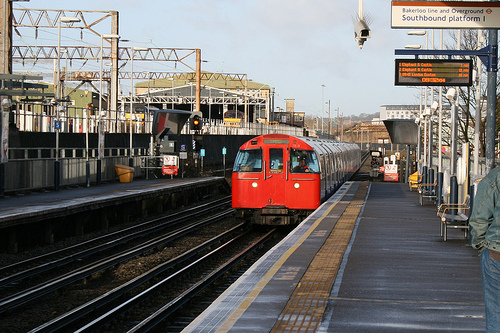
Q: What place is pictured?
A: It is a station.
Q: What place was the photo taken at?
A: It was taken at the station.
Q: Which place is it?
A: It is a station.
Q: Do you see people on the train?
A: Yes, there is a person on the train.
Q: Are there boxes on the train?
A: No, there is a person on the train.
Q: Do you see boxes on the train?
A: No, there is a person on the train.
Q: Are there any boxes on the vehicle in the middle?
A: No, there is a person on the train.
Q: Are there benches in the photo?
A: Yes, there is a bench.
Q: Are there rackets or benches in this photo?
A: Yes, there is a bench.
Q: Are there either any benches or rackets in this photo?
A: Yes, there is a bench.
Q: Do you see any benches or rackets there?
A: Yes, there is a bench.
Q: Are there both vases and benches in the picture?
A: No, there is a bench but no vases.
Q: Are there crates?
A: No, there are no crates.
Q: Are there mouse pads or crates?
A: No, there are no crates or mouse pads.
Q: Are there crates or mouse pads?
A: No, there are no crates or mouse pads.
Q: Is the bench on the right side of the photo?
A: Yes, the bench is on the right of the image.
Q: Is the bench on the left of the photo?
A: No, the bench is on the right of the image.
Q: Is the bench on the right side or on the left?
A: The bench is on the right of the image.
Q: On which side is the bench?
A: The bench is on the right of the image.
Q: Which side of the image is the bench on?
A: The bench is on the right of the image.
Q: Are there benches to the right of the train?
A: Yes, there is a bench to the right of the train.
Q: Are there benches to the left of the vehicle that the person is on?
A: No, the bench is to the right of the train.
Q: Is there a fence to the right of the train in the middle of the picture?
A: No, there is a bench to the right of the train.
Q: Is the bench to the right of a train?
A: Yes, the bench is to the right of a train.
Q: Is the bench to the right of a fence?
A: No, the bench is to the right of a train.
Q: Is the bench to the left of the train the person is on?
A: No, the bench is to the right of the train.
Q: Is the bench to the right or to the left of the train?
A: The bench is to the right of the train.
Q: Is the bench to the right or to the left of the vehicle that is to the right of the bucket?
A: The bench is to the right of the train.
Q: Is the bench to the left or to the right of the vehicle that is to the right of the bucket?
A: The bench is to the right of the train.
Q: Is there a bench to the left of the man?
A: Yes, there is a bench to the left of the man.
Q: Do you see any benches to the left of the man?
A: Yes, there is a bench to the left of the man.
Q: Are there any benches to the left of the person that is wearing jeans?
A: Yes, there is a bench to the left of the man.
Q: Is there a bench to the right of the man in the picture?
A: No, the bench is to the left of the man.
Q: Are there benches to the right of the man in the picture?
A: No, the bench is to the left of the man.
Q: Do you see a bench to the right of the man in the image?
A: No, the bench is to the left of the man.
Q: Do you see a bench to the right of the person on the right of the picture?
A: No, the bench is to the left of the man.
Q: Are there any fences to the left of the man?
A: No, there is a bench to the left of the man.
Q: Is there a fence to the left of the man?
A: No, there is a bench to the left of the man.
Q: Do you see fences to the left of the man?
A: No, there is a bench to the left of the man.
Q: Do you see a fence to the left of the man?
A: No, there is a bench to the left of the man.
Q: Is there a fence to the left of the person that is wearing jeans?
A: No, there is a bench to the left of the man.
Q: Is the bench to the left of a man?
A: Yes, the bench is to the left of a man.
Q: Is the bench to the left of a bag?
A: No, the bench is to the left of a man.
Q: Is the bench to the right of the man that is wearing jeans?
A: No, the bench is to the left of the man.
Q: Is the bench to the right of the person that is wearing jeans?
A: No, the bench is to the left of the man.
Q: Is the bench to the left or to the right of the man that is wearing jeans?
A: The bench is to the left of the man.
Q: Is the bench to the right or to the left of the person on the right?
A: The bench is to the left of the man.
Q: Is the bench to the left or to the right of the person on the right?
A: The bench is to the left of the man.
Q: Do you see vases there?
A: No, there are no vases.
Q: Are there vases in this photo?
A: No, there are no vases.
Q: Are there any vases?
A: No, there are no vases.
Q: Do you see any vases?
A: No, there are no vases.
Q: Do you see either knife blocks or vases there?
A: No, there are no vases or knife blocks.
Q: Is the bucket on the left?
A: Yes, the bucket is on the left of the image.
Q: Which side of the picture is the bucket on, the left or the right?
A: The bucket is on the left of the image.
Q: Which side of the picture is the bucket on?
A: The bucket is on the left of the image.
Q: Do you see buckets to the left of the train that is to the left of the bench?
A: Yes, there is a bucket to the left of the train.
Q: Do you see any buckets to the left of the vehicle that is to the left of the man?
A: Yes, there is a bucket to the left of the train.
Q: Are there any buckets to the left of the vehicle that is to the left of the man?
A: Yes, there is a bucket to the left of the train.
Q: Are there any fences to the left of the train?
A: No, there is a bucket to the left of the train.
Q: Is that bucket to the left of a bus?
A: No, the bucket is to the left of the train.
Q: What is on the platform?
A: The bucket is on the platform.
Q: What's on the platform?
A: The bucket is on the platform.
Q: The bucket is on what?
A: The bucket is on the platform.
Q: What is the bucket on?
A: The bucket is on the platform.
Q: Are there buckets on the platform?
A: Yes, there is a bucket on the platform.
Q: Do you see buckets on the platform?
A: Yes, there is a bucket on the platform.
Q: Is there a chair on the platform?
A: No, there is a bucket on the platform.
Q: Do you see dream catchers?
A: No, there are no dream catchers.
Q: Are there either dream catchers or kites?
A: No, there are no dream catchers or kites.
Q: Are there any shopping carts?
A: No, there are no shopping carts.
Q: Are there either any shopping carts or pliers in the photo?
A: No, there are no shopping carts or pliers.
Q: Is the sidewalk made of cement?
A: Yes, the sidewalk is made of cement.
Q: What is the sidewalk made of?
A: The side walk is made of concrete.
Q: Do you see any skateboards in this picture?
A: No, there are no skateboards.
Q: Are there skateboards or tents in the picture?
A: No, there are no skateboards or tents.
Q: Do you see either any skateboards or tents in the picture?
A: No, there are no skateboards or tents.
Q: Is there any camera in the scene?
A: Yes, there is a camera.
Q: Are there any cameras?
A: Yes, there is a camera.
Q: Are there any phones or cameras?
A: Yes, there is a camera.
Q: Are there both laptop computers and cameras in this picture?
A: No, there is a camera but no laptops.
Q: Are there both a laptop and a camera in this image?
A: No, there is a camera but no laptops.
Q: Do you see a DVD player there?
A: No, there are no DVD players.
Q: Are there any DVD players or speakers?
A: No, there are no DVD players or speakers.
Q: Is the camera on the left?
A: No, the camera is on the right of the image.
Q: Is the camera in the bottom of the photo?
A: No, the camera is in the top of the image.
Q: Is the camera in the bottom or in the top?
A: The camera is in the top of the image.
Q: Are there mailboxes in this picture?
A: No, there are no mailboxes.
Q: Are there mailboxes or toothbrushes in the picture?
A: No, there are no mailboxes or toothbrushes.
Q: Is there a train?
A: Yes, there is a train.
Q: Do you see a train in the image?
A: Yes, there is a train.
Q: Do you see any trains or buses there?
A: Yes, there is a train.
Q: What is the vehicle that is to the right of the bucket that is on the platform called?
A: The vehicle is a train.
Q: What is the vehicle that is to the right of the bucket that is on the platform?
A: The vehicle is a train.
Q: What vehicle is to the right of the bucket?
A: The vehicle is a train.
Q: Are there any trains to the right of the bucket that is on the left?
A: Yes, there is a train to the right of the bucket.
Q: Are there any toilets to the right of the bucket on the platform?
A: No, there is a train to the right of the bucket.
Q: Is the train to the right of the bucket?
A: Yes, the train is to the right of the bucket.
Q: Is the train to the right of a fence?
A: No, the train is to the right of the bucket.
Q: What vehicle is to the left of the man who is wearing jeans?
A: The vehicle is a train.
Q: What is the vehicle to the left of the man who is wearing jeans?
A: The vehicle is a train.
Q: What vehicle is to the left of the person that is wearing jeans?
A: The vehicle is a train.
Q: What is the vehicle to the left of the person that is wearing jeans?
A: The vehicle is a train.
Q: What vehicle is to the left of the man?
A: The vehicle is a train.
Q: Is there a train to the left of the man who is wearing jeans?
A: Yes, there is a train to the left of the man.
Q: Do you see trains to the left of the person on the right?
A: Yes, there is a train to the left of the man.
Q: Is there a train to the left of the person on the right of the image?
A: Yes, there is a train to the left of the man.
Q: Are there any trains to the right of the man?
A: No, the train is to the left of the man.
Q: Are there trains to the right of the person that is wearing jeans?
A: No, the train is to the left of the man.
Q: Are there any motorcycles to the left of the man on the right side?
A: No, there is a train to the left of the man.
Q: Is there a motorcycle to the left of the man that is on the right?
A: No, there is a train to the left of the man.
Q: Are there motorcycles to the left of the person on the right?
A: No, there is a train to the left of the man.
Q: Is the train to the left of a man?
A: Yes, the train is to the left of a man.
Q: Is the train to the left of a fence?
A: No, the train is to the left of a man.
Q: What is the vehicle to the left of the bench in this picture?
A: The vehicle is a train.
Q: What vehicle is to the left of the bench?
A: The vehicle is a train.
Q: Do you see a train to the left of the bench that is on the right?
A: Yes, there is a train to the left of the bench.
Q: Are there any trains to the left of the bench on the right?
A: Yes, there is a train to the left of the bench.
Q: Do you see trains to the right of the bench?
A: No, the train is to the left of the bench.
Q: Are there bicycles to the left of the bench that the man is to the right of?
A: No, there is a train to the left of the bench.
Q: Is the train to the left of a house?
A: No, the train is to the left of a bench.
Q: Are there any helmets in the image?
A: No, there are no helmets.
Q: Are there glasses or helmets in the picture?
A: No, there are no helmets or glasses.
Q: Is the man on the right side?
A: Yes, the man is on the right of the image.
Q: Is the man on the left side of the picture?
A: No, the man is on the right of the image.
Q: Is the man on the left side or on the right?
A: The man is on the right of the image.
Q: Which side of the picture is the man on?
A: The man is on the right of the image.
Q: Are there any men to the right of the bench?
A: Yes, there is a man to the right of the bench.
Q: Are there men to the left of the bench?
A: No, the man is to the right of the bench.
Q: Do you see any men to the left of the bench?
A: No, the man is to the right of the bench.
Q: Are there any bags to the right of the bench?
A: No, there is a man to the right of the bench.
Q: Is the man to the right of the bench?
A: Yes, the man is to the right of the bench.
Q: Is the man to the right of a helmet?
A: No, the man is to the right of the bench.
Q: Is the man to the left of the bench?
A: No, the man is to the right of the bench.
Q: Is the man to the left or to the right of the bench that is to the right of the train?
A: The man is to the right of the bench.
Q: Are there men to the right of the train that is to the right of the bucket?
A: Yes, there is a man to the right of the train.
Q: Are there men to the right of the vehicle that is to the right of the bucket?
A: Yes, there is a man to the right of the train.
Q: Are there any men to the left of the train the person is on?
A: No, the man is to the right of the train.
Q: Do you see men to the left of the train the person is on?
A: No, the man is to the right of the train.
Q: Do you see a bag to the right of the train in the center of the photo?
A: No, there is a man to the right of the train.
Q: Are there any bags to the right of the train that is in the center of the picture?
A: No, there is a man to the right of the train.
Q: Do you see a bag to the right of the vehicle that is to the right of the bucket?
A: No, there is a man to the right of the train.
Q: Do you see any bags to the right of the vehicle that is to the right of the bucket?
A: No, there is a man to the right of the train.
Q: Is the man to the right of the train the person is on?
A: Yes, the man is to the right of the train.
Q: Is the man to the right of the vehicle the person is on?
A: Yes, the man is to the right of the train.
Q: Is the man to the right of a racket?
A: No, the man is to the right of the train.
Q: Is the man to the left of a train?
A: No, the man is to the right of a train.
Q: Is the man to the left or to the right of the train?
A: The man is to the right of the train.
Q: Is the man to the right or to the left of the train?
A: The man is to the right of the train.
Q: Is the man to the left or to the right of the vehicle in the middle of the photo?
A: The man is to the right of the train.